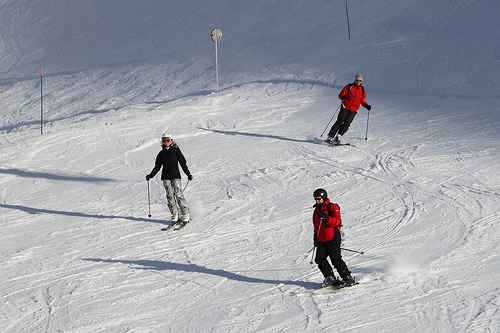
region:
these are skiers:
[87, 54, 422, 256]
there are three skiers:
[175, 42, 482, 275]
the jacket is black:
[142, 132, 227, 225]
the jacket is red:
[333, 57, 390, 120]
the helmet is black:
[272, 171, 349, 231]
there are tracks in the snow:
[72, 231, 243, 318]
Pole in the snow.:
[35, 62, 46, 138]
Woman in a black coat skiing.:
[142, 129, 199, 234]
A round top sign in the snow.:
[209, 24, 224, 92]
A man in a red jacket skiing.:
[307, 185, 352, 295]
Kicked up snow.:
[376, 248, 421, 288]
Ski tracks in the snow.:
[357, 147, 484, 238]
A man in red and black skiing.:
[325, 67, 374, 153]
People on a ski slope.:
[142, 65, 409, 294]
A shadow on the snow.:
[81, 248, 306, 279]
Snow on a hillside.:
[4, 0, 206, 56]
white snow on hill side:
[9, 194, 49, 232]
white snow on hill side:
[213, 277, 247, 307]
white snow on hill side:
[411, 291, 458, 319]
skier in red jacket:
[291, 176, 352, 289]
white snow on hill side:
[424, 126, 472, 156]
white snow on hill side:
[222, 166, 261, 203]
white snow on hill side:
[241, 95, 276, 137]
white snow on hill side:
[90, 98, 123, 123]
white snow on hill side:
[22, 162, 70, 193]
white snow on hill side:
[49, 181, 104, 228]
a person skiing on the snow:
[264, 188, 386, 328]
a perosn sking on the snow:
[143, 126, 235, 244]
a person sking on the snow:
[308, 73, 404, 173]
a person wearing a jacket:
[303, 55, 375, 140]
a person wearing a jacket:
[297, 167, 391, 312]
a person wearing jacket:
[112, 115, 232, 242]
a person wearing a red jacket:
[304, 184, 376, 301]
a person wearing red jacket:
[312, 42, 403, 137]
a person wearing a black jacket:
[114, 120, 271, 268]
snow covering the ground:
[114, 229, 258, 329]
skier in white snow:
[135, 126, 193, 233]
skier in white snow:
[291, 185, 363, 290]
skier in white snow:
[325, 68, 376, 143]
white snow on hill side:
[1, 243, 65, 271]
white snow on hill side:
[170, 292, 224, 314]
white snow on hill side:
[381, 236, 435, 283]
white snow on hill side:
[212, 176, 257, 216]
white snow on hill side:
[371, 158, 442, 205]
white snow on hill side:
[237, 69, 277, 106]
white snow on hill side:
[41, 138, 89, 193]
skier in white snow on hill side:
[135, 126, 200, 244]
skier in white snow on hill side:
[298, 176, 369, 293]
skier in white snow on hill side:
[317, 48, 384, 149]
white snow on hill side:
[44, 228, 121, 273]